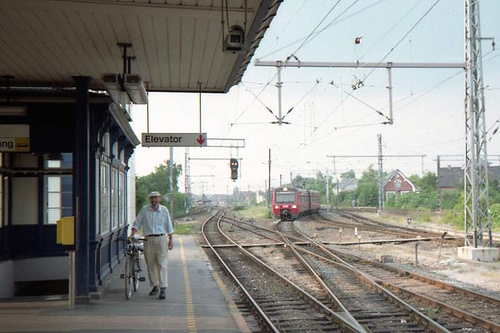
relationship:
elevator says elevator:
[145, 135, 183, 144] [145, 132, 187, 143]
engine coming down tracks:
[269, 188, 322, 219] [201, 204, 499, 331]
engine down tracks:
[269, 188, 322, 219] [201, 204, 499, 331]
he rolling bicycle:
[128, 192, 175, 299] [116, 237, 145, 304]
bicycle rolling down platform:
[116, 237, 145, 304] [7, 236, 247, 332]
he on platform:
[128, 192, 175, 299] [7, 236, 247, 332]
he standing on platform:
[128, 192, 175, 299] [7, 236, 247, 332]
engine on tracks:
[269, 188, 322, 219] [196, 204, 498, 333]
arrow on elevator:
[198, 133, 206, 148] [145, 135, 183, 144]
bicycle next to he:
[121, 235, 150, 305] [128, 192, 175, 299]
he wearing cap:
[128, 192, 175, 299] [148, 191, 161, 197]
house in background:
[376, 168, 419, 205] [131, 4, 500, 240]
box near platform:
[55, 216, 75, 249] [7, 236, 247, 332]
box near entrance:
[55, 216, 75, 249] [3, 251, 74, 299]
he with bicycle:
[128, 192, 175, 299] [116, 237, 145, 304]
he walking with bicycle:
[128, 192, 175, 299] [116, 237, 145, 304]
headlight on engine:
[291, 205, 297, 209] [269, 188, 322, 219]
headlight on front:
[291, 205, 297, 209] [271, 185, 300, 215]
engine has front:
[269, 188, 322, 219] [271, 185, 300, 215]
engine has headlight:
[269, 188, 322, 219] [274, 203, 283, 212]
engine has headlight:
[269, 188, 322, 219] [293, 196, 301, 207]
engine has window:
[269, 188, 322, 219] [272, 187, 297, 202]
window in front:
[272, 187, 297, 202] [271, 185, 300, 215]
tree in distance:
[353, 168, 384, 207] [132, 1, 499, 237]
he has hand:
[128, 192, 175, 299] [166, 238, 174, 248]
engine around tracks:
[269, 188, 322, 219] [201, 204, 499, 331]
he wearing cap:
[128, 192, 175, 299] [144, 187, 163, 196]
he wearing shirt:
[128, 192, 175, 299] [130, 203, 173, 241]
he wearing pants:
[128, 192, 175, 299] [141, 233, 169, 288]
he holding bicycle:
[128, 192, 175, 299] [121, 235, 150, 305]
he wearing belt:
[128, 192, 175, 299] [144, 229, 170, 240]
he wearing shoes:
[128, 192, 175, 299] [148, 279, 163, 301]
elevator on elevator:
[145, 135, 183, 144] [145, 135, 183, 144]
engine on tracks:
[269, 188, 322, 219] [201, 204, 499, 331]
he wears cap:
[135, 185, 176, 296] [148, 191, 161, 197]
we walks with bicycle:
[135, 185, 176, 296] [116, 237, 145, 304]